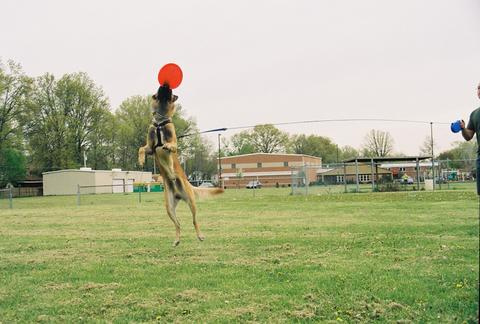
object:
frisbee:
[156, 62, 184, 90]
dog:
[135, 82, 224, 247]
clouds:
[3, 6, 474, 72]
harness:
[148, 121, 170, 154]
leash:
[175, 118, 459, 147]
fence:
[3, 177, 311, 204]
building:
[39, 168, 153, 197]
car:
[246, 180, 262, 188]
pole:
[217, 132, 223, 189]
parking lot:
[195, 175, 317, 189]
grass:
[22, 227, 480, 324]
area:
[2, 184, 479, 324]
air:
[0, 0, 476, 196]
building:
[217, 153, 322, 187]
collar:
[151, 114, 171, 127]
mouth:
[159, 82, 170, 88]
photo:
[1, 1, 480, 321]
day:
[9, 3, 480, 148]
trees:
[3, 62, 201, 184]